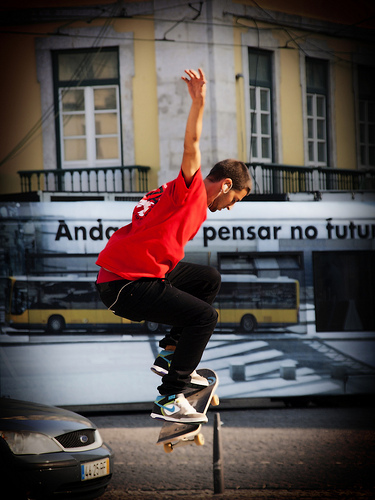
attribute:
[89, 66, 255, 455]
boy — doing skateboard trick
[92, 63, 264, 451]
man — skateboarding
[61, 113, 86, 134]
glass pane — small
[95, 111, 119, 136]
small pane — glass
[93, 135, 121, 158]
small pane — glass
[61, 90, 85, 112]
glass pane — small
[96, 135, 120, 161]
glass — small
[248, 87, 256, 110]
glass — small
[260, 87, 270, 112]
glass — small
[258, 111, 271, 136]
glass — small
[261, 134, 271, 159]
glass — small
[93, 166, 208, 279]
shirt — red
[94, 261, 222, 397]
pants — black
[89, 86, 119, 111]
glass — small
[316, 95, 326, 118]
glass — small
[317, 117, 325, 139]
glass — small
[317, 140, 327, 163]
glass — small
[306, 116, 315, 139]
glass — small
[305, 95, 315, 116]
glass — small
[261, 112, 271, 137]
glass — small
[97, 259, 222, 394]
jeans — black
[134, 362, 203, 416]
shoe — grey, white, blue, athletic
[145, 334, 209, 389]
shoe — athletic, grey, white, blue